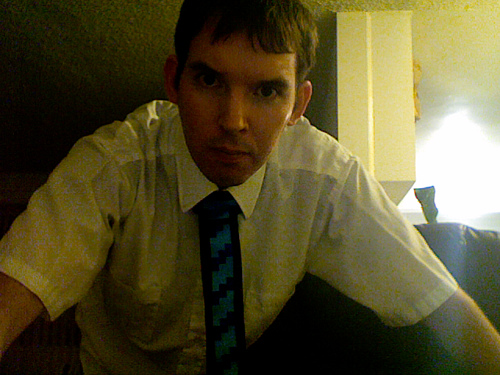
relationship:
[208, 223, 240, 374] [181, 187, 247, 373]
pattern on tie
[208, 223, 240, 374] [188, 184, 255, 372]
pattern on tie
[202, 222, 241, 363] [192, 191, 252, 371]
pattern going down tie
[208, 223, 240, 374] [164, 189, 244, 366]
pattern going down tie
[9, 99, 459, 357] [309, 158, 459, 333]
shirt with sleeve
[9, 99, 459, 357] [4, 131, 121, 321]
shirt with sleeve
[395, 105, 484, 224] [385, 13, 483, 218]
light on wall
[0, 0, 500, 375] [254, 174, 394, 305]
man wears a shirt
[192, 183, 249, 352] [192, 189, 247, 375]
tie has tie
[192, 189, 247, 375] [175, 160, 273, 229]
tie around collar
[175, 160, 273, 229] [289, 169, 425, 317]
collar of shirt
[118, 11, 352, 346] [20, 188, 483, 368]
man has extended arms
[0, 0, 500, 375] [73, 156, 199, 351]
man wears a shirt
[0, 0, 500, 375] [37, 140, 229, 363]
man wears a shirt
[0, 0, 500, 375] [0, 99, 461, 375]
man wears a shirt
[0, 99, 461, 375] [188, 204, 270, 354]
shirt and tie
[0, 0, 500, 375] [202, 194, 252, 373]
man has a tie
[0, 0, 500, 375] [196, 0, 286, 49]
man has hair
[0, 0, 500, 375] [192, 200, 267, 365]
man has tie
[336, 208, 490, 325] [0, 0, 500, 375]
couch behind man